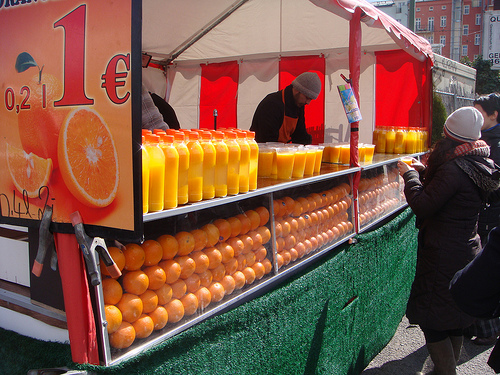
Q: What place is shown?
A: It is a shop.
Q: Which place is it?
A: It is a shop.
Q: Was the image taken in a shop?
A: Yes, it was taken in a shop.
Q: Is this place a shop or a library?
A: It is a shop.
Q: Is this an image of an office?
A: No, the picture is showing a shop.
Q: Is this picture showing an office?
A: No, the picture is showing a shop.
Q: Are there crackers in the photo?
A: No, there are no crackers.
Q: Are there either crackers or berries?
A: No, there are no crackers or berries.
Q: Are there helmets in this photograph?
A: No, there are no helmets.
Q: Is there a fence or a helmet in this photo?
A: No, there are no helmets or fences.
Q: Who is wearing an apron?
A: The man is wearing an apron.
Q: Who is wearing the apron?
A: The man is wearing an apron.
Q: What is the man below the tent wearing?
A: The man is wearing an apron.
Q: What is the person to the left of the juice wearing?
A: The man is wearing an apron.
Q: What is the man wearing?
A: The man is wearing an apron.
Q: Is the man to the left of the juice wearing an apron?
A: Yes, the man is wearing an apron.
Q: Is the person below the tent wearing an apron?
A: Yes, the man is wearing an apron.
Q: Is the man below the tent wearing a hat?
A: No, the man is wearing an apron.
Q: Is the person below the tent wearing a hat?
A: No, the man is wearing an apron.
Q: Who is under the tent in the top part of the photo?
A: The man is under the tent.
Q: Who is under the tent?
A: The man is under the tent.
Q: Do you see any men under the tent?
A: Yes, there is a man under the tent.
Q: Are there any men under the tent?
A: Yes, there is a man under the tent.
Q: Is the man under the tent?
A: Yes, the man is under the tent.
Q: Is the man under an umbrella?
A: No, the man is under the tent.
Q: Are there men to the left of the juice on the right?
A: Yes, there is a man to the left of the juice.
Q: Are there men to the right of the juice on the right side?
A: No, the man is to the left of the juice.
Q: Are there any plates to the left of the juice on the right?
A: No, there is a man to the left of the juice.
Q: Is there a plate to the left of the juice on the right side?
A: No, there is a man to the left of the juice.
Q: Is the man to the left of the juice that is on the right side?
A: Yes, the man is to the left of the juice.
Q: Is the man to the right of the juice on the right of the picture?
A: No, the man is to the left of the juice.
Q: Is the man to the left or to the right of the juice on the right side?
A: The man is to the left of the juice.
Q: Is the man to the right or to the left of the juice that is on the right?
A: The man is to the left of the juice.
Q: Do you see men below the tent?
A: Yes, there is a man below the tent.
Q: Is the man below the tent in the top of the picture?
A: Yes, the man is below the tent.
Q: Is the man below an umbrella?
A: No, the man is below the tent.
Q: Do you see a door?
A: Yes, there is a door.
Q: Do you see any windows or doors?
A: Yes, there is a door.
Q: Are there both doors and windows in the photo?
A: Yes, there are both a door and windows.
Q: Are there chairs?
A: No, there are no chairs.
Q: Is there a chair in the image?
A: No, there are no chairs.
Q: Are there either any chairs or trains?
A: No, there are no chairs or trains.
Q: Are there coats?
A: Yes, there is a coat.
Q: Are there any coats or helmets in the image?
A: Yes, there is a coat.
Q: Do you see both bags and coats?
A: No, there is a coat but no bags.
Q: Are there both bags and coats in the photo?
A: No, there is a coat but no bags.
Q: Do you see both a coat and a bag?
A: No, there is a coat but no bags.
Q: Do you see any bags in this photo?
A: No, there are no bags.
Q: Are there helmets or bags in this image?
A: No, there are no bags or helmets.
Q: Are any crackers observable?
A: No, there are no crackers.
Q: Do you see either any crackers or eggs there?
A: No, there are no crackers or eggs.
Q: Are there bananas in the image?
A: No, there are no bananas.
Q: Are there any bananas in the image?
A: No, there are no bananas.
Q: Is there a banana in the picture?
A: No, there are no bananas.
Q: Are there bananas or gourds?
A: No, there are no bananas or gourds.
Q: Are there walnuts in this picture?
A: No, there are no walnuts.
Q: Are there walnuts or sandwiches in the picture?
A: No, there are no walnuts or sandwiches.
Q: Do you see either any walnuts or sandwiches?
A: No, there are no walnuts or sandwiches.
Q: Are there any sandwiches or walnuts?
A: No, there are no walnuts or sandwiches.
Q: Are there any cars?
A: No, there are no cars.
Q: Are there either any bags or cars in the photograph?
A: No, there are no cars or bags.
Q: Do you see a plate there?
A: No, there are no plates.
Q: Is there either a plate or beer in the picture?
A: No, there are no plates or beer.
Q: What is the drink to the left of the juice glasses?
A: The drink is juice.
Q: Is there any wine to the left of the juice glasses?
A: No, there is juice to the left of the glasses.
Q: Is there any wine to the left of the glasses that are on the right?
A: No, there is juice to the left of the glasses.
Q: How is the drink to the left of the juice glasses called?
A: The drink is juice.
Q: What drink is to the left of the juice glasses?
A: The drink is juice.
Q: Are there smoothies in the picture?
A: No, there are no smoothies.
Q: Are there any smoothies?
A: No, there are no smoothies.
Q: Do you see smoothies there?
A: No, there are no smoothies.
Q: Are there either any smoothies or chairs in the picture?
A: No, there are no smoothies or chairs.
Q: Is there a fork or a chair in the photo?
A: No, there are no chairs or forks.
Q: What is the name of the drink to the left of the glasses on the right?
A: The drink is juice.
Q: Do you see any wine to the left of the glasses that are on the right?
A: No, there is juice to the left of the glasses.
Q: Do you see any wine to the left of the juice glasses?
A: No, there is juice to the left of the glasses.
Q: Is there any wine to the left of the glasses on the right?
A: No, there is juice to the left of the glasses.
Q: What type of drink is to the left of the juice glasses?
A: The drink is juice.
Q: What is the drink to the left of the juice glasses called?
A: The drink is juice.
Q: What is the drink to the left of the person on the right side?
A: The drink is juice.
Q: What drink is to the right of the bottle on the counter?
A: The drink is juice.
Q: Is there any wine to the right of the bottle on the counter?
A: No, there is juice to the right of the bottle.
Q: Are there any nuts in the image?
A: No, there are no nuts.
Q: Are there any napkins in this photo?
A: No, there are no napkins.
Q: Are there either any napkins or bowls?
A: No, there are no napkins or bowls.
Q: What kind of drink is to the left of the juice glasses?
A: The drink is juice.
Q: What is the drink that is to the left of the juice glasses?
A: The drink is juice.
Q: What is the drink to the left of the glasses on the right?
A: The drink is juice.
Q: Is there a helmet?
A: No, there are no helmets.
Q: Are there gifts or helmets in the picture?
A: No, there are no helmets or gifts.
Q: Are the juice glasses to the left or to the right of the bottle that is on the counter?
A: The glasses are to the right of the bottle.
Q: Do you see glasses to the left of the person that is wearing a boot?
A: Yes, there are glasses to the left of the person.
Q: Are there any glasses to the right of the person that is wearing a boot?
A: No, the glasses are to the left of the person.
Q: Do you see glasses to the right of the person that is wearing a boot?
A: No, the glasses are to the left of the person.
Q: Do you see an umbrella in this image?
A: No, there are no umbrellas.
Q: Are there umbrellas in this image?
A: No, there are no umbrellas.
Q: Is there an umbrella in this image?
A: No, there are no umbrellas.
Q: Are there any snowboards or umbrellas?
A: No, there are no umbrellas or snowboards.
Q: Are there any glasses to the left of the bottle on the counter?
A: No, the glasses are to the right of the bottle.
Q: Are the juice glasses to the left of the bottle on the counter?
A: No, the glasses are to the right of the bottle.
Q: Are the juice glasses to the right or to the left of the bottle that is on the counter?
A: The glasses are to the right of the bottle.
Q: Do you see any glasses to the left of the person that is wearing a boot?
A: Yes, there are glasses to the left of the person.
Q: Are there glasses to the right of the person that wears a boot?
A: No, the glasses are to the left of the person.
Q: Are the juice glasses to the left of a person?
A: Yes, the glasses are to the left of a person.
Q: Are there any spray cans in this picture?
A: No, there are no spray cans.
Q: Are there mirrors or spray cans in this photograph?
A: No, there are no spray cans or mirrors.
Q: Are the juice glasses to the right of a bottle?
A: Yes, the glasses are to the right of a bottle.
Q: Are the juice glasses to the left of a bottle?
A: No, the glasses are to the right of a bottle.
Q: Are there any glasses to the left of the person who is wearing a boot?
A: Yes, there are glasses to the left of the person.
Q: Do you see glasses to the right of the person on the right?
A: No, the glasses are to the left of the person.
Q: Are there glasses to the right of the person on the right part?
A: No, the glasses are to the left of the person.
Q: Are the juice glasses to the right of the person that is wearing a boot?
A: No, the glasses are to the left of the person.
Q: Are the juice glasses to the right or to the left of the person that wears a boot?
A: The glasses are to the left of the person.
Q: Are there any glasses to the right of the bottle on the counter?
A: Yes, there are glasses to the right of the bottle.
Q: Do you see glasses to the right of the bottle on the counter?
A: Yes, there are glasses to the right of the bottle.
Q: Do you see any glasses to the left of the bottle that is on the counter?
A: No, the glasses are to the right of the bottle.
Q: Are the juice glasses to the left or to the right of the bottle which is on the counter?
A: The glasses are to the right of the bottle.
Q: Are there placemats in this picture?
A: No, there are no placemats.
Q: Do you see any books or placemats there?
A: No, there are no placemats or books.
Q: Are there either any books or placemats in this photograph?
A: No, there are no placemats or books.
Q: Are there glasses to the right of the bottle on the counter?
A: Yes, there are glasses to the right of the bottle.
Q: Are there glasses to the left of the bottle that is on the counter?
A: No, the glasses are to the right of the bottle.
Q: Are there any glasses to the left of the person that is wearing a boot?
A: Yes, there are glasses to the left of the person.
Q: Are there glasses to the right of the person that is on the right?
A: No, the glasses are to the left of the person.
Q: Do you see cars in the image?
A: No, there are no cars.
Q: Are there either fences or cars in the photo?
A: No, there are no cars or fences.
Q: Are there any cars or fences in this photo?
A: No, there are no cars or fences.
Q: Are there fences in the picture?
A: No, there are no fences.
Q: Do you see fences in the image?
A: No, there are no fences.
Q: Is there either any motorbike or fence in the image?
A: No, there are no fences or motorcycles.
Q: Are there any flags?
A: No, there are no flags.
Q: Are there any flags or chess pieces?
A: No, there are no flags or chess pieces.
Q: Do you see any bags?
A: No, there are no bags.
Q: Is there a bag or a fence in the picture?
A: No, there are no bags or fences.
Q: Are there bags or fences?
A: No, there are no bags or fences.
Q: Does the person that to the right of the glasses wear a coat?
A: Yes, the person wears a coat.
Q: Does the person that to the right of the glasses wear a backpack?
A: No, the person wears a coat.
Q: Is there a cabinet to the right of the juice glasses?
A: No, there is a person to the right of the glasses.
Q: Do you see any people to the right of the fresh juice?
A: Yes, there is a person to the right of the juice.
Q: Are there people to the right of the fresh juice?
A: Yes, there is a person to the right of the juice.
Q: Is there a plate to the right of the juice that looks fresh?
A: No, there is a person to the right of the juice.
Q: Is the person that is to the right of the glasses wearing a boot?
A: Yes, the person is wearing a boot.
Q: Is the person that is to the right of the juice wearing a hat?
A: No, the person is wearing a boot.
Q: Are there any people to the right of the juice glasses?
A: Yes, there is a person to the right of the glasses.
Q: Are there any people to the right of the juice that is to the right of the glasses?
A: Yes, there is a person to the right of the juice.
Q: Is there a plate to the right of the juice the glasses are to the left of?
A: No, there is a person to the right of the juice.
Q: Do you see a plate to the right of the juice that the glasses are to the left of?
A: No, there is a person to the right of the juice.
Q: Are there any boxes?
A: No, there are no boxes.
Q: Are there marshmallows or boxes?
A: No, there are no boxes or marshmallows.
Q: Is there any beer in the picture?
A: No, there is no beer.